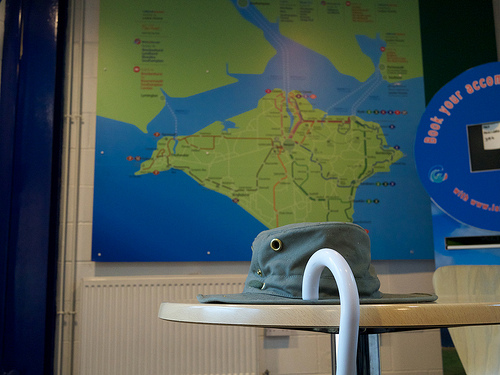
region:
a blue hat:
[190, 218, 442, 305]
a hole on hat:
[267, 233, 284, 254]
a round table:
[147, 296, 494, 374]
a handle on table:
[299, 248, 364, 373]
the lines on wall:
[76, 280, 261, 372]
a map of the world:
[90, 9, 438, 264]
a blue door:
[0, 3, 68, 370]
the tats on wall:
[91, 250, 217, 258]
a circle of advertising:
[408, 54, 498, 246]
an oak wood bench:
[430, 261, 499, 374]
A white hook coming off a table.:
[299, 250, 358, 374]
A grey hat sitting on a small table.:
[195, 220, 439, 304]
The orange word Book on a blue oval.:
[425, 114, 445, 144]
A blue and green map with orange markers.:
[91, 1, 439, 263]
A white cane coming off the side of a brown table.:
[302, 247, 360, 374]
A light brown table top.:
[153, 297, 499, 328]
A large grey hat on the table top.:
[194, 221, 439, 303]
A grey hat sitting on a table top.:
[194, 220, 439, 300]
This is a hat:
[263, 189, 497, 325]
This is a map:
[157, 159, 278, 232]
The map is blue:
[163, 183, 259, 282]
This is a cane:
[299, 236, 352, 373]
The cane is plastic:
[311, 307, 360, 351]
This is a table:
[369, 308, 444, 339]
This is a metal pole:
[49, 307, 110, 339]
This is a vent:
[100, 319, 142, 350]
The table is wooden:
[399, 282, 459, 349]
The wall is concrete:
[74, 232, 98, 269]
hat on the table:
[170, 167, 430, 357]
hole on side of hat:
[256, 227, 292, 268]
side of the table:
[228, 300, 279, 325]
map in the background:
[180, 120, 366, 221]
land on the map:
[192, 126, 372, 221]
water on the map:
[117, 194, 189, 254]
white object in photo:
[293, 251, 379, 360]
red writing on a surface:
[393, 81, 489, 166]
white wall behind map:
[69, 163, 90, 210]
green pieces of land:
[137, 25, 369, 194]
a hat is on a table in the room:
[155, 218, 498, 330]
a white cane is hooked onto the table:
[296, 248, 358, 374]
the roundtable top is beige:
[160, 296, 497, 338]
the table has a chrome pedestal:
[154, 294, 499, 373]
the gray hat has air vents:
[198, 220, 440, 311]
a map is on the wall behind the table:
[91, 5, 438, 267]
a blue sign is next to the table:
[411, 55, 499, 273]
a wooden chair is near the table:
[431, 259, 499, 369]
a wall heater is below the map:
[65, 269, 305, 373]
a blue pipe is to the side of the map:
[2, 2, 54, 372]